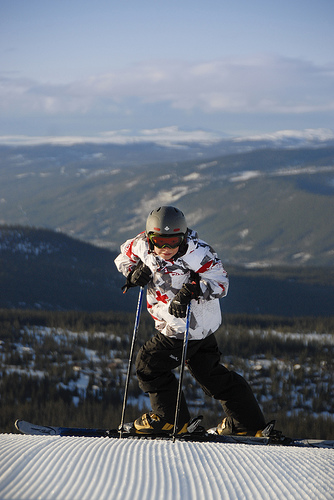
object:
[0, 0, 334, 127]
sky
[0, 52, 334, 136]
clouds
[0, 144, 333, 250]
mountains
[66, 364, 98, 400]
snow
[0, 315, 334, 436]
ground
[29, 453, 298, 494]
lines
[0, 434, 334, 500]
snow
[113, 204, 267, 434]
person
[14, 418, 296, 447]
skis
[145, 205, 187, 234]
helmet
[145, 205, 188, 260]
head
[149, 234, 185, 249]
goggles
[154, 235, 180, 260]
face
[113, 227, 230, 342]
jacket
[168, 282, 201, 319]
glove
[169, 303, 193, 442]
pole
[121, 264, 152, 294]
glove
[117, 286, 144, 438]
pole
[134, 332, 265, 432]
trouser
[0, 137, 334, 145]
horizon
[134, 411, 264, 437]
ski boots